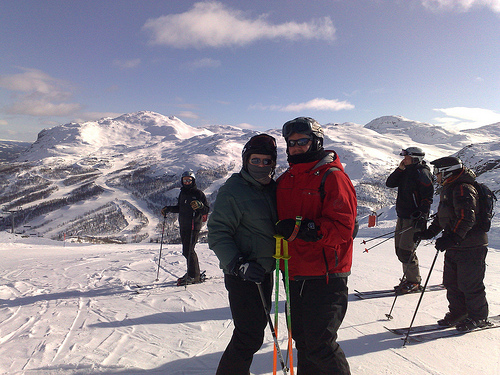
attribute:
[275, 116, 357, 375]
man — skiing, standing still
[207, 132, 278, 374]
woman — standing still, skiing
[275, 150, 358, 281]
ski coat — red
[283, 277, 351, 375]
ski pants — black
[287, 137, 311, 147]
sunglasses — black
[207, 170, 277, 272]
ski coat — grey, greenish gray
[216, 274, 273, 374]
ski pants — black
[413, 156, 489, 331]
man — skiing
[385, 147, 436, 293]
person — skiing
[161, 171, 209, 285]
person — skiing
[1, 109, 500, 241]
mountains — snowy, snow-covered, snow capped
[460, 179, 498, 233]
backpack — black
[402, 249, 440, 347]
ski pole — black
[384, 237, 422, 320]
ski pole — black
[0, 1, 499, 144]
sky — blue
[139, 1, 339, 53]
cloud — fluffy, light, white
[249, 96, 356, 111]
cloud — fluffy, light, white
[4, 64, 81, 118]
cloud — white, fluffy, light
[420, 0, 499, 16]
cloud — fluffy, light, white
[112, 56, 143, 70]
cloud — fluffy, light, white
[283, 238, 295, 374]
ski pole — green, bright, orange, neon, pastel, multi-colored, multicolored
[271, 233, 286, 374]
ski pole — green, bright, orange, neon, multicolored, pastel, multi-colored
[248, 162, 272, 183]
scarf — gray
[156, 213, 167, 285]
ski pole — black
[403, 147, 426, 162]
helmet — white